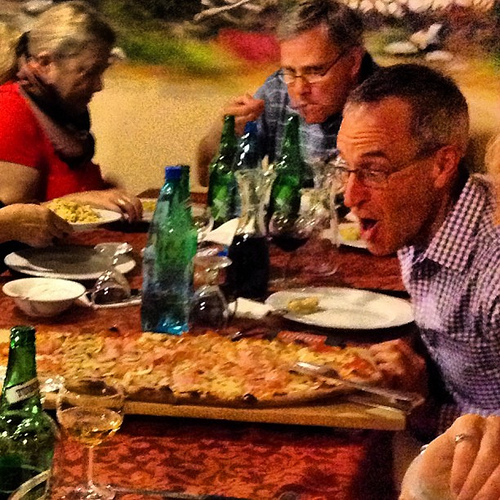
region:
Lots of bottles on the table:
[133, 98, 325, 340]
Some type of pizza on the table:
[25, 305, 409, 408]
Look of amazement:
[308, 43, 493, 334]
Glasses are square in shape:
[311, 135, 408, 211]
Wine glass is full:
[48, 362, 147, 498]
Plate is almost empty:
[262, 268, 436, 345]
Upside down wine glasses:
[71, 226, 248, 339]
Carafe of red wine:
[218, 163, 300, 307]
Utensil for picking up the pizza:
[285, 350, 432, 423]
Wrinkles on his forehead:
[321, 110, 417, 162]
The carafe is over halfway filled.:
[221, 160, 280, 306]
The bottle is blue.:
[140, 164, 195, 334]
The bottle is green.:
[1, 319, 59, 499]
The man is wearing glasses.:
[318, 57, 474, 264]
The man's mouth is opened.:
[328, 58, 475, 260]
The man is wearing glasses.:
[272, 0, 368, 127]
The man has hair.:
[336, 60, 473, 261]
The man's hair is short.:
[331, 58, 473, 260]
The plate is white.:
[263, 280, 418, 332]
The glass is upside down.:
[89, 238, 139, 322]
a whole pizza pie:
[0, 327, 368, 401]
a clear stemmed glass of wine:
[58, 375, 125, 498]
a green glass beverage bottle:
[1, 326, 56, 496]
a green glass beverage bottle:
[208, 111, 236, 221]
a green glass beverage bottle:
[274, 112, 305, 216]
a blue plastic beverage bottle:
[139, 165, 189, 331]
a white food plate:
[267, 283, 415, 331]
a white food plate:
[1, 245, 138, 276]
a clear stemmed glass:
[189, 253, 229, 335]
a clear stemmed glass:
[92, 241, 129, 327]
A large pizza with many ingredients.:
[0, 326, 380, 403]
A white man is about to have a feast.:
[335, 62, 499, 498]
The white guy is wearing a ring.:
[453, 432, 479, 442]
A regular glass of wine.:
[55, 374, 127, 497]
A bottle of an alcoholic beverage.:
[0, 325, 56, 498]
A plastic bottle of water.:
[140, 163, 193, 333]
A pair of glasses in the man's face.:
[330, 155, 424, 190]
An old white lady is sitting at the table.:
[0, 4, 143, 246]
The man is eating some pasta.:
[195, 0, 380, 188]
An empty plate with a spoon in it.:
[265, 285, 415, 328]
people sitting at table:
[9, 16, 494, 397]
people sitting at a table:
[12, 8, 499, 396]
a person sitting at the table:
[2, 6, 497, 495]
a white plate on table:
[214, 221, 431, 413]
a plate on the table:
[212, 207, 425, 387]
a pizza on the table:
[2, 232, 442, 497]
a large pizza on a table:
[14, 256, 396, 499]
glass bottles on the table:
[101, 58, 368, 334]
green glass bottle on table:
[112, 66, 349, 376]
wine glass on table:
[49, 356, 174, 498]